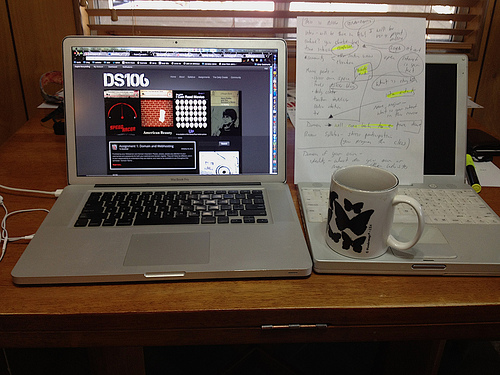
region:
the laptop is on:
[68, 71, 292, 271]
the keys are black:
[92, 185, 272, 239]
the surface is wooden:
[164, 288, 396, 353]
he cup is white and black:
[329, 168, 449, 258]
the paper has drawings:
[315, 67, 417, 164]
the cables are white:
[7, 178, 42, 242]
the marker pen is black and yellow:
[466, 155, 488, 193]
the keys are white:
[418, 185, 496, 225]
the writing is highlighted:
[347, 118, 407, 139]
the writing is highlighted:
[386, 80, 421, 102]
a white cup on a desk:
[322, 160, 432, 277]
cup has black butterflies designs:
[321, 157, 426, 270]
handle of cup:
[384, 188, 430, 260]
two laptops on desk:
[5, 5, 498, 325]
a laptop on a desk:
[6, 27, 315, 295]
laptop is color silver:
[5, 26, 312, 291]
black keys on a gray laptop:
[5, 172, 315, 279]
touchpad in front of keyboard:
[115, 226, 220, 271]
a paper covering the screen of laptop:
[280, 5, 470, 195]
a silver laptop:
[286, 35, 496, 280]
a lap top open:
[9, 27, 302, 289]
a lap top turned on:
[22, 32, 291, 295]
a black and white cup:
[326, 159, 407, 262]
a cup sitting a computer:
[329, 164, 429, 261]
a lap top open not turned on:
[305, 44, 476, 274]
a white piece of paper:
[299, 21, 424, 178]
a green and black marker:
[462, 156, 479, 188]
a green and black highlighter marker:
[467, 156, 485, 192]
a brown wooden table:
[36, 280, 472, 350]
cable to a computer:
[7, 194, 42, 252]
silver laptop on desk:
[3, 15, 317, 302]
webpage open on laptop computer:
[69, 46, 279, 182]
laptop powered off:
[292, 14, 497, 303]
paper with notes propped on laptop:
[270, 9, 437, 209]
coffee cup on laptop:
[320, 162, 415, 272]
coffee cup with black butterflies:
[320, 157, 412, 257]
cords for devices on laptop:
[0, 165, 61, 260]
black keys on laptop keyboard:
[55, 153, 283, 263]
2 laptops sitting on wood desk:
[10, 5, 481, 373]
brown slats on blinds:
[73, 1, 490, 67]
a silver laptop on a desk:
[38, 41, 288, 306]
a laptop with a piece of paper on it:
[313, 49, 476, 274]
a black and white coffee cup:
[323, 167, 414, 267]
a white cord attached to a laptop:
[0, 182, 63, 207]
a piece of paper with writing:
[285, 14, 435, 189]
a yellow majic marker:
[461, 143, 483, 203]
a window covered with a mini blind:
[68, 6, 480, 38]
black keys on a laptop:
[72, 187, 276, 234]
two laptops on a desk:
[43, 44, 480, 211]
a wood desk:
[4, 281, 488, 322]